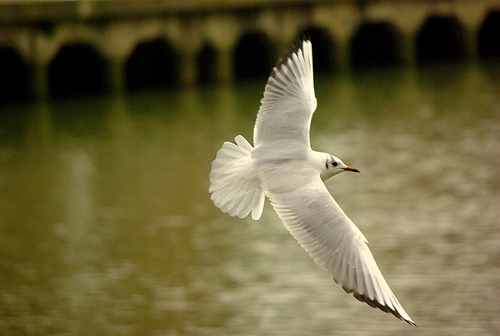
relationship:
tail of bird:
[211, 131, 263, 221] [206, 39, 418, 330]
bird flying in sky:
[206, 39, 418, 330] [5, 3, 497, 333]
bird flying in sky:
[206, 39, 418, 330] [4, 99, 498, 167]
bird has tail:
[206, 39, 418, 330] [202, 122, 269, 238]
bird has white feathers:
[225, 54, 411, 322] [219, 184, 263, 216]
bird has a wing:
[225, 54, 411, 322] [286, 200, 412, 322]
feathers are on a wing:
[219, 184, 263, 216] [286, 200, 412, 322]